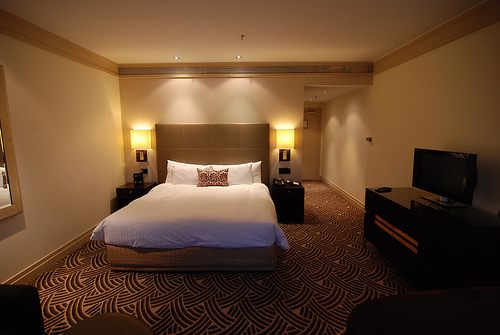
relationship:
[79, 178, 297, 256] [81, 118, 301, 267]
comforter on bed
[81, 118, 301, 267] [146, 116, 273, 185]
bed has headbed